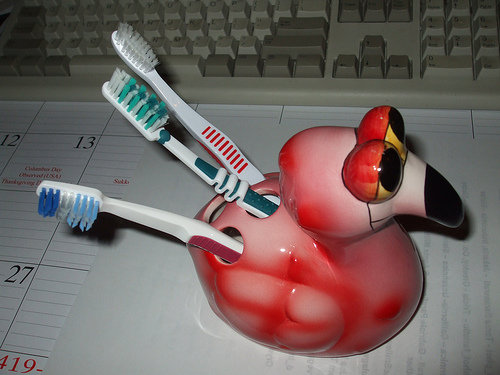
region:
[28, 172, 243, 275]
toothbrush with blue bristles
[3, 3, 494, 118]
tan computer key board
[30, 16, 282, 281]
group of three different toothbrushes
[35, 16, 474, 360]
red bird toothbrush holder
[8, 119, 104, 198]
thirteenth of the month on calendar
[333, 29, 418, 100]
arrow keys on computer keyboard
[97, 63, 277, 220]
green and white toothbrush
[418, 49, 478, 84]
zero key on keyboard number pad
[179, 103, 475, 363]
bird shaped toothbrush holder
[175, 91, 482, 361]
red toothbrush stand shaped like bird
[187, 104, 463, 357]
toothbrush holder in the shape of a flamingo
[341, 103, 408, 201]
flamingo's large eyes are protruding on its head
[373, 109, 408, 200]
flamingo's eyes are yellow and black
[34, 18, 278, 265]
three toothbrushes in separate holes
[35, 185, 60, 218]
dark blue brush bristles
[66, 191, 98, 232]
light blue brush bristles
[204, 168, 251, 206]
toothbrush handle has a zigzag design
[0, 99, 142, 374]
section of a monthly planner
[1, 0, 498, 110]
part of a keyboard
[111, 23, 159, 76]
brush with all white bristles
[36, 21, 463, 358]
the toothbrushes sticking out of the holder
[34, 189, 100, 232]
the blue and white bristles on the brush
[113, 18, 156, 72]
the white bristles on the brush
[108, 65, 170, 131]
the bristles on the brush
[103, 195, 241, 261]
the handle for the toothbrush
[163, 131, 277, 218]
the handle for the toothbrush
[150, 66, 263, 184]
the handle for the toothbrush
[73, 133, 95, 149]
the number 13 on the calendar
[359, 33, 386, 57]
the key on the keyboard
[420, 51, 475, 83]
the number 0 key on the keyboard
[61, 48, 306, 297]
three toothbrushes close together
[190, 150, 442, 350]
ceramic holder for toothbrushes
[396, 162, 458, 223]
black beak on cup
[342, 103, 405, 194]
red and yellow eyes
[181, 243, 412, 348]
red and pink body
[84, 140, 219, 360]
white paper under holder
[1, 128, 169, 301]
white calendar under paper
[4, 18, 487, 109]
white keyboard behind holder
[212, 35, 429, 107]
grey keys on keyboard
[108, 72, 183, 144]
green and white bristles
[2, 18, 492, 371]
a pink tooth brush holder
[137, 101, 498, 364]
the tooth brush holder is a flamingo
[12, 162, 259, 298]
this toothbrush has a red grip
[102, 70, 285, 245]
this tooth brush has a green grip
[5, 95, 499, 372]
a large desk calendar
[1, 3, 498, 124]
an old computer keyboard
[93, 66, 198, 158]
this toothbrush has green and white bristles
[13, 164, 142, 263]
this tooth brush has blue and white bristles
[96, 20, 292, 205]
this toothbrush is white and red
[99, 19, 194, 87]
this tooth brush has white bristles